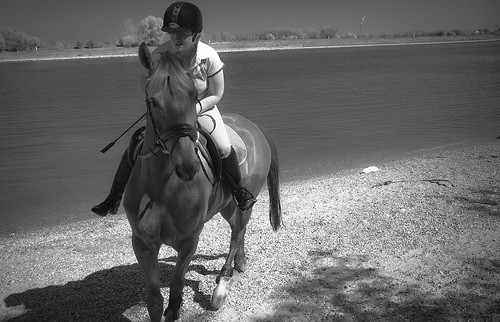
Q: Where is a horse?
A: Near water.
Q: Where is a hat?
A: On person's head.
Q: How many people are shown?
A: 1.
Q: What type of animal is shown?
A: Horse.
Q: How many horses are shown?
A: 1.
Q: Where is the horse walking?
A: Shore.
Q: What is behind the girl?
A: Water.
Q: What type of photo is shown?
A: Black and white.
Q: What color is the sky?
A: Gray.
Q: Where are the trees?
A: Background.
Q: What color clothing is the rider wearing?
A: White.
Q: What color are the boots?
A: Black.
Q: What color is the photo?
A: Black and white.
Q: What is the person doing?
A: Riding a horse.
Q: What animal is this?
A: Horse.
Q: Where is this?
A: Along the river.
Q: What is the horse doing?
A: Walking.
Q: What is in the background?
A: Trees.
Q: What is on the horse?
A: A human.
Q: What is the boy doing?
A: Horse riding.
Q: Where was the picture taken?
A: Near the water.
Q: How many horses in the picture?
A: One.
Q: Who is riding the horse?
A: Young child.